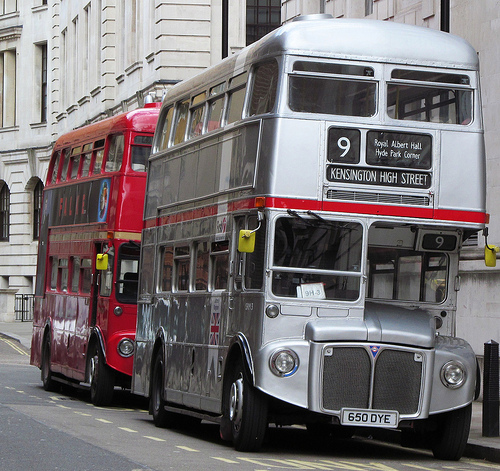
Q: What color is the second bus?
A: Red.